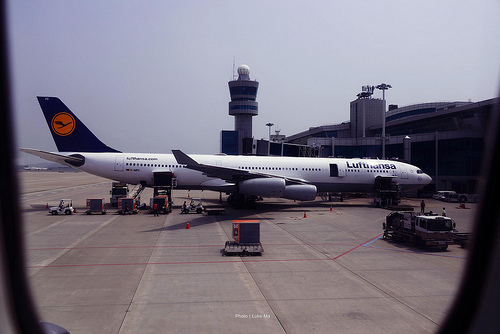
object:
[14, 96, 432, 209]
plane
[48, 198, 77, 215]
truck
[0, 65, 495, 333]
airport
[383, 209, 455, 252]
vehicle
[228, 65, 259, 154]
statue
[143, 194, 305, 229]
shadow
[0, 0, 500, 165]
sky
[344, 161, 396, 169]
name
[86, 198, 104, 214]
objects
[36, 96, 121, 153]
tail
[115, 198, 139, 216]
luggage cart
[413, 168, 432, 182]
cockpit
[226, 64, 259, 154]
tower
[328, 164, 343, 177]
door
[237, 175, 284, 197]
engine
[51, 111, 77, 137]
logo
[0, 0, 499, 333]
photo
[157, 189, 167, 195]
baggage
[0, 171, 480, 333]
ground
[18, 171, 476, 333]
runway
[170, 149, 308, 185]
wing